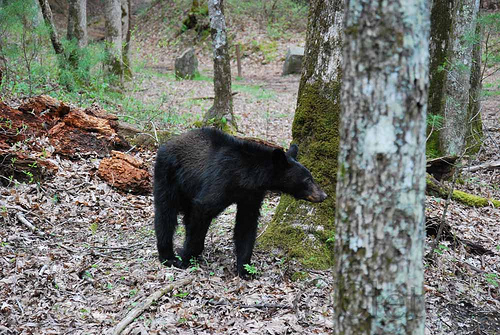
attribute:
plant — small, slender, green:
[424, 9, 494, 269]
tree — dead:
[0, 90, 148, 189]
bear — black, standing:
[149, 123, 334, 280]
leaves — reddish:
[0, 12, 500, 334]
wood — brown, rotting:
[28, 97, 56, 123]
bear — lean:
[153, 132, 334, 269]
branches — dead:
[1, 81, 497, 327]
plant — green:
[256, 80, 341, 280]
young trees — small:
[1, 1, 141, 104]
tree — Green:
[306, 15, 480, 313]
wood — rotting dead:
[0, 92, 126, 180]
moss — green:
[258, 78, 338, 265]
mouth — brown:
[301, 185, 328, 205]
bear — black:
[153, 130, 323, 259]